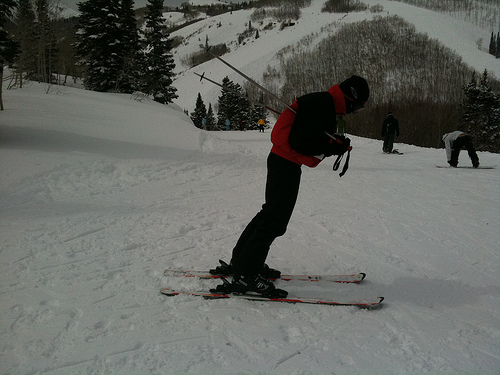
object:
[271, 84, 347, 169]
winter clothes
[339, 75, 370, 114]
ski mask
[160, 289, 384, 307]
skis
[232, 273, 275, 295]
boots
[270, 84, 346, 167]
jacket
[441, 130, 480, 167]
person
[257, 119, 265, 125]
jacket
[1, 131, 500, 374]
tracks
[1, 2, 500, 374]
snow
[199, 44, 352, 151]
ski poles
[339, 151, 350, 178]
straps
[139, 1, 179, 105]
trees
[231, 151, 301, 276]
ski pants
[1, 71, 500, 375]
downhill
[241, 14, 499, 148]
trees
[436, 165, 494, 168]
snowboard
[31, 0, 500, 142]
mountain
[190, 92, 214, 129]
trees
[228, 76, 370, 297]
people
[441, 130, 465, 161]
grey jacket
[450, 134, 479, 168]
black pants